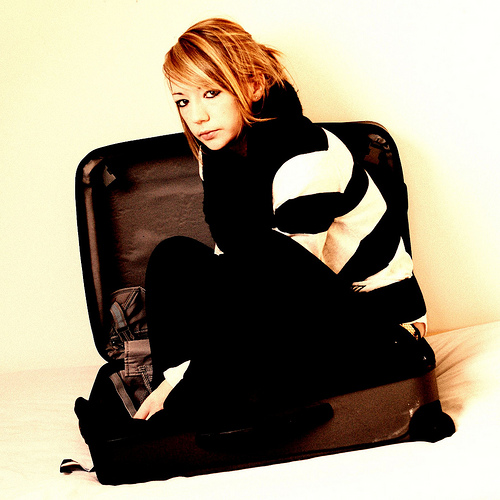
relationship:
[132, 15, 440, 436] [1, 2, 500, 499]
girl in a room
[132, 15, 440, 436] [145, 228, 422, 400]
girl wearing pants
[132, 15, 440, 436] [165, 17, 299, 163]
girl has red hair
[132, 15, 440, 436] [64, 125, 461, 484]
girl in suitcase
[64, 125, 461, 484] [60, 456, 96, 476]
suitcase has tags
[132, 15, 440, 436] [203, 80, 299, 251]
girl has a scarf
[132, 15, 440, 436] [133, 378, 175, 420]
girl has a hand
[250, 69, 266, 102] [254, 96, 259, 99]
left ear has an earring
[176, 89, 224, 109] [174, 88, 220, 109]
eyes have eyeliner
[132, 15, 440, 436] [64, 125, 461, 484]
girl sitting in suitcase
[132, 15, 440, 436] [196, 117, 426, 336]
girl wearing sweater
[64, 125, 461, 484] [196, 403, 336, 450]
suitcase has a handle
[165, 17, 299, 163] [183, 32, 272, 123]
red hair has highlights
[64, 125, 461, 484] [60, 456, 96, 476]
suitcase has a clasp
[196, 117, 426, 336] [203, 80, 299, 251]
sweater has a scarf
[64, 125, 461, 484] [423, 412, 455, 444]
suitcase has a wheel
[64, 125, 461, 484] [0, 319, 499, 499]
suitcase on a bed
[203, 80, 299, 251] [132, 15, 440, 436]
scarf worn by girl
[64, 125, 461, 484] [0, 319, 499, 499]
suitcase on bed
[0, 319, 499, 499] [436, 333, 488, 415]
bed has wrinkles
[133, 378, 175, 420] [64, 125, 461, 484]
hand in suitcase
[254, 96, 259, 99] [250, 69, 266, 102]
earring in left ear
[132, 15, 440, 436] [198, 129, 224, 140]
girl has lips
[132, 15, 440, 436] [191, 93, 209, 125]
girl has a nose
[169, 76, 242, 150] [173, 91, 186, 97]
face has an eyebrow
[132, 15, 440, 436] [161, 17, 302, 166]
girl has red hair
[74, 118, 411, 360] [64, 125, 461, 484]
lid on suitcase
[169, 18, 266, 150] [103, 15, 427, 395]
head of girl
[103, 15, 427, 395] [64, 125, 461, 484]
girl sitting suitcase